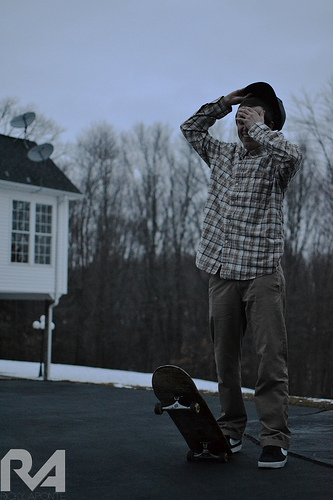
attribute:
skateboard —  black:
[150, 364, 236, 461]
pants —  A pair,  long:
[204, 252, 302, 461]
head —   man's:
[226, 89, 290, 153]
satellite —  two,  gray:
[24, 138, 61, 164]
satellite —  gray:
[6, 105, 38, 131]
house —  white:
[1, 133, 82, 334]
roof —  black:
[1, 129, 86, 199]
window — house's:
[4, 201, 68, 296]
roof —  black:
[2, 133, 85, 205]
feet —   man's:
[258, 445, 287, 467]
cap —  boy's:
[244, 80, 284, 126]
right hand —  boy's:
[235, 103, 262, 130]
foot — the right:
[220, 426, 245, 452]